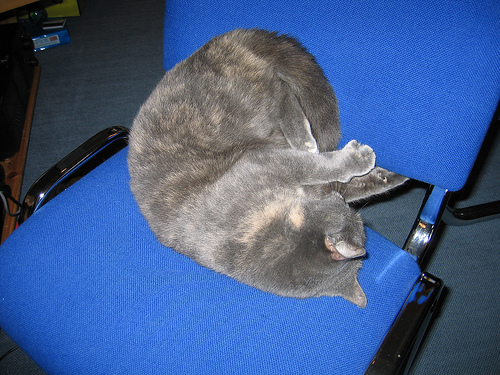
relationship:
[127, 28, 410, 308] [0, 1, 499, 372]
cat on chair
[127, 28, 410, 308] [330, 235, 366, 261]
cat has ear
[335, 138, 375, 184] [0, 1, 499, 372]
paw on chair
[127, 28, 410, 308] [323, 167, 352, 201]
cat has whiskers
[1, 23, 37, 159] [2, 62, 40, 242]
electronics on shelf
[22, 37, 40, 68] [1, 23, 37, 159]
dials on electronics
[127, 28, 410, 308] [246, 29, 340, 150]
cat has tail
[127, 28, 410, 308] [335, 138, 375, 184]
cat has paw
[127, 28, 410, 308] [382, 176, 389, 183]
cat has claws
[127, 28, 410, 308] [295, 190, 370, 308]
cat has head